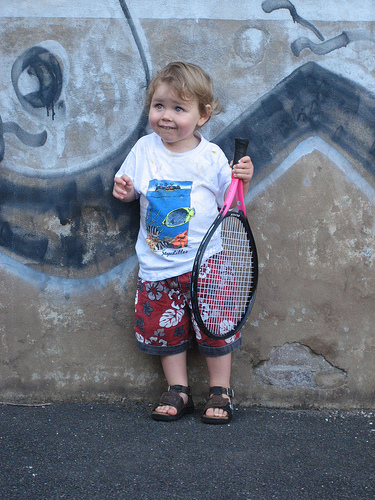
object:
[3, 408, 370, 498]
floor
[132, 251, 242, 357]
shorts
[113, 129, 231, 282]
shirt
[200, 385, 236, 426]
sandals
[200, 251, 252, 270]
strings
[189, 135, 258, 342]
racket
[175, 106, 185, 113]
eye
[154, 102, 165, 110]
eye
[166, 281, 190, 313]
flower design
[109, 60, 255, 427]
boy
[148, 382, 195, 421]
sandals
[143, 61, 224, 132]
hair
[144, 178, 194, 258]
artwork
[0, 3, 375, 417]
wall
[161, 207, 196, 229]
fish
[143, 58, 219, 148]
head